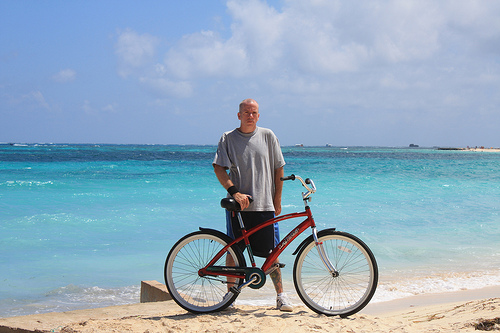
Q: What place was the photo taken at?
A: It was taken at the ocean.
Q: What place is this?
A: It is an ocean.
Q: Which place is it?
A: It is an ocean.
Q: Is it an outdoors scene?
A: Yes, it is outdoors.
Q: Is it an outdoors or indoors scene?
A: It is outdoors.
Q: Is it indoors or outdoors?
A: It is outdoors.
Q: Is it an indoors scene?
A: No, it is outdoors.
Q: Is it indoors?
A: No, it is outdoors.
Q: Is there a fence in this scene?
A: No, there are no fences.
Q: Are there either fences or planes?
A: No, there are no fences or planes.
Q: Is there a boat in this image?
A: No, there are no boats.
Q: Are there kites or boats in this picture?
A: No, there are no boats or kites.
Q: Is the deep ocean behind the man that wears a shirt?
A: Yes, the ocean is behind the man.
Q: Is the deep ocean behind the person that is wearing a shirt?
A: Yes, the ocean is behind the man.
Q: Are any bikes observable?
A: Yes, there is a bike.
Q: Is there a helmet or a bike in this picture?
A: Yes, there is a bike.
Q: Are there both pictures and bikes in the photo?
A: No, there is a bike but no pictures.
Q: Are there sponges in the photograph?
A: No, there are no sponges.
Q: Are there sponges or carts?
A: No, there are no sponges or carts.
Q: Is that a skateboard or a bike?
A: That is a bike.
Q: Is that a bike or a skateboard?
A: That is a bike.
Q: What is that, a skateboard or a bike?
A: That is a bike.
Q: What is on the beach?
A: The bike is on the beach.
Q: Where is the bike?
A: The bike is on the beach.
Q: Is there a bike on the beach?
A: Yes, there is a bike on the beach.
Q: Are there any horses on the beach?
A: No, there is a bike on the beach.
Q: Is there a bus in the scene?
A: No, there are no buses.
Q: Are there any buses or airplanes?
A: No, there are no buses or airplanes.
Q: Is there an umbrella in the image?
A: No, there are no umbrellas.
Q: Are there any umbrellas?
A: No, there are no umbrellas.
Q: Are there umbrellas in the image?
A: No, there are no umbrellas.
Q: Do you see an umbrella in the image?
A: No, there are no umbrellas.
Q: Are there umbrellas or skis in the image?
A: No, there are no umbrellas or skis.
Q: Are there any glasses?
A: No, there are no glasses.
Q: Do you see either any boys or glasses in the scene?
A: No, there are no glasses or boys.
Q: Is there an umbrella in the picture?
A: No, there are no umbrellas.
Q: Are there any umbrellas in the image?
A: No, there are no umbrellas.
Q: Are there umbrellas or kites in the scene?
A: No, there are no umbrellas or kites.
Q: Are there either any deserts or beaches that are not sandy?
A: No, there is a beach but it is sandy.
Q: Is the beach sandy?
A: Yes, the beach is sandy.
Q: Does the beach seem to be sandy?
A: Yes, the beach is sandy.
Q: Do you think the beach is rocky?
A: No, the beach is sandy.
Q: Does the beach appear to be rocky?
A: No, the beach is sandy.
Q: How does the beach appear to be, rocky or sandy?
A: The beach is sandy.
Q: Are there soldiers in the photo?
A: No, there are no soldiers.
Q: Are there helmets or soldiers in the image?
A: No, there are no soldiers or helmets.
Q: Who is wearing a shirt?
A: The man is wearing a shirt.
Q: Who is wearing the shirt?
A: The man is wearing a shirt.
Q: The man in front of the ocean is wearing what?
A: The man is wearing a shirt.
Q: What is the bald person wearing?
A: The man is wearing a shirt.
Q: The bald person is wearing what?
A: The man is wearing a shirt.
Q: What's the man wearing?
A: The man is wearing a shirt.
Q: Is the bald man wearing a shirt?
A: Yes, the man is wearing a shirt.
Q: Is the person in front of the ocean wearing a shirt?
A: Yes, the man is wearing a shirt.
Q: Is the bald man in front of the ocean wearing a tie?
A: No, the man is wearing a shirt.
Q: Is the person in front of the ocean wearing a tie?
A: No, the man is wearing a shirt.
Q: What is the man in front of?
A: The man is in front of the ocean.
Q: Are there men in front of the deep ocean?
A: Yes, there is a man in front of the ocean.